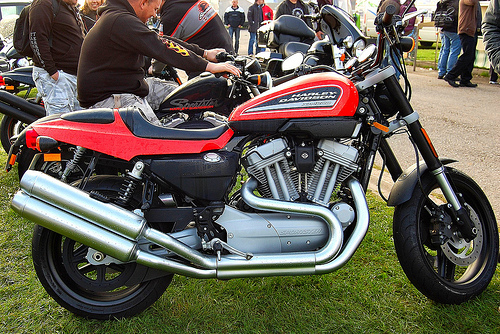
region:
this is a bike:
[11, 13, 486, 324]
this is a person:
[80, 4, 208, 124]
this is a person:
[12, 6, 91, 117]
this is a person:
[227, 2, 249, 57]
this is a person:
[247, 6, 276, 47]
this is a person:
[379, 2, 419, 54]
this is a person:
[432, 5, 462, 72]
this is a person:
[450, 3, 481, 88]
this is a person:
[479, 11, 498, 48]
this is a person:
[163, 10, 249, 100]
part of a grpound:
[358, 268, 376, 295]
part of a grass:
[357, 273, 381, 310]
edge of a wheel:
[408, 248, 432, 282]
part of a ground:
[338, 276, 365, 323]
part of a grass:
[354, 269, 368, 297]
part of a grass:
[355, 258, 370, 284]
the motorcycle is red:
[99, 126, 152, 153]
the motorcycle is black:
[193, 88, 223, 104]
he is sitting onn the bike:
[76, 76, 175, 123]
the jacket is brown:
[458, 8, 472, 29]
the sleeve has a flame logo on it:
[154, 33, 193, 65]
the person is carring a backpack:
[10, 1, 59, 61]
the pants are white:
[46, 86, 66, 114]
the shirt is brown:
[57, 19, 79, 50]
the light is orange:
[413, 124, 444, 161]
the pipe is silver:
[252, 244, 304, 279]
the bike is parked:
[16, 1, 491, 306]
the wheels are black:
[389, 158, 496, 305]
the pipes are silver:
[10, 171, 371, 294]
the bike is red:
[19, 67, 374, 198]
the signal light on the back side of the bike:
[27, 125, 69, 163]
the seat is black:
[70, 87, 243, 162]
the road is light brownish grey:
[420, 75, 496, 172]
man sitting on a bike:
[51, 2, 240, 97]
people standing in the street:
[223, 0, 493, 101]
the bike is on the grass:
[20, 62, 483, 312]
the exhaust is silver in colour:
[5, 157, 185, 287]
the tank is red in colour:
[224, 66, 370, 141]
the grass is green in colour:
[221, 288, 383, 323]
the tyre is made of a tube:
[361, 159, 488, 331]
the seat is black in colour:
[90, 104, 250, 157]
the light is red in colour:
[2, 127, 80, 158]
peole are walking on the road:
[426, 0, 497, 98]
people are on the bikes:
[69, 1, 269, 103]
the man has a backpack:
[6, 0, 101, 117]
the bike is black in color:
[187, 84, 228, 118]